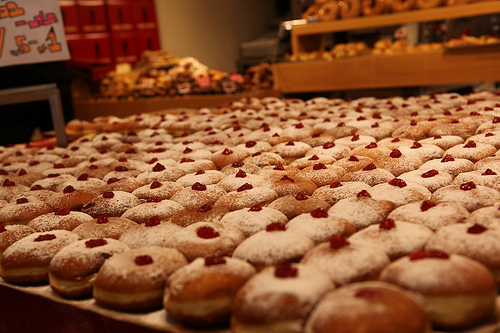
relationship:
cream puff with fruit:
[108, 245, 176, 305] [130, 249, 159, 270]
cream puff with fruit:
[47, 229, 123, 300] [81, 237, 110, 253]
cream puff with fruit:
[7, 224, 75, 284] [34, 227, 60, 247]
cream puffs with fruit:
[94, 93, 485, 158] [229, 93, 399, 142]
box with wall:
[66, 2, 153, 70] [63, 8, 253, 71]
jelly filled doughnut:
[270, 264, 300, 280] [239, 294, 299, 320]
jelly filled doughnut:
[270, 264, 300, 280] [244, 286, 280, 312]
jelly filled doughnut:
[270, 264, 300, 280] [236, 273, 281, 319]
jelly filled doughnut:
[270, 264, 300, 280] [253, 297, 280, 317]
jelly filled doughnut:
[270, 264, 300, 280] [241, 284, 283, 316]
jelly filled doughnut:
[270, 264, 300, 280] [249, 283, 277, 313]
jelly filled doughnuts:
[270, 264, 300, 280] [171, 282, 278, 316]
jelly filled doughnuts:
[196, 248, 225, 268] [116, 279, 282, 324]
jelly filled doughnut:
[270, 264, 300, 280] [167, 283, 288, 323]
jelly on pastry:
[266, 264, 291, 277] [167, 270, 240, 311]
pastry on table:
[244, 293, 294, 320] [123, 309, 153, 325]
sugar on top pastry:
[315, 259, 355, 273] [224, 287, 294, 315]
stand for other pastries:
[305, 27, 449, 71] [314, 34, 395, 57]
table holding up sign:
[10, 76, 50, 96] [3, 5, 61, 71]